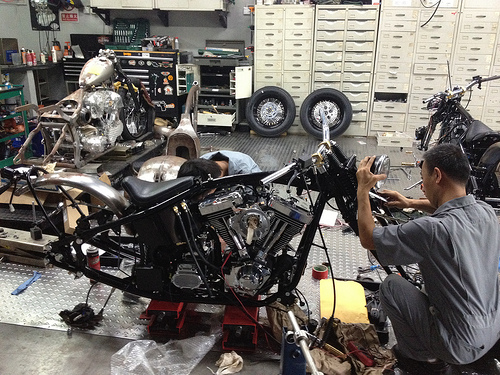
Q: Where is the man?
A: In the right corner of the picture.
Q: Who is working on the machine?
A: The man in the work clothes.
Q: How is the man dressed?
A: In a work romper.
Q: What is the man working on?
A: A machine.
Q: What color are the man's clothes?
A: Gray.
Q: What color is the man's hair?
A: Black.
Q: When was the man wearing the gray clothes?
A: While he was working on the machine.